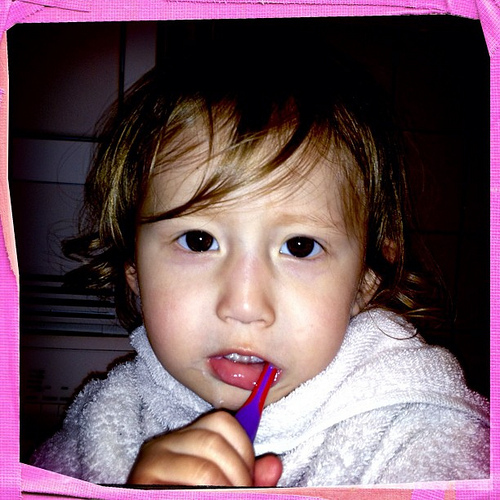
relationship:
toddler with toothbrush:
[18, 32, 481, 474] [227, 350, 286, 449]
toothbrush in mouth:
[227, 350, 286, 449] [210, 345, 282, 388]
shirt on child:
[88, 322, 460, 482] [18, 32, 481, 474]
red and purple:
[258, 387, 269, 412] [245, 406, 257, 429]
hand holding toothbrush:
[139, 409, 257, 488] [227, 350, 286, 449]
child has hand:
[18, 32, 481, 474] [139, 409, 257, 488]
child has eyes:
[18, 32, 481, 474] [174, 230, 329, 264]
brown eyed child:
[187, 232, 214, 249] [18, 32, 481, 474]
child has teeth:
[18, 32, 481, 474] [224, 350, 268, 366]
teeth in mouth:
[224, 350, 268, 366] [210, 345, 282, 388]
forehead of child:
[166, 114, 341, 208] [18, 32, 481, 474]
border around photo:
[2, 1, 498, 31] [18, 32, 481, 474]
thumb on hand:
[256, 449, 283, 485] [139, 409, 257, 488]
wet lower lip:
[228, 367, 257, 383] [214, 357, 265, 387]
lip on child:
[214, 357, 265, 387] [18, 32, 481, 474]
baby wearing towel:
[18, 32, 481, 474] [88, 322, 460, 482]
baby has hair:
[18, 32, 481, 474] [95, 63, 430, 318]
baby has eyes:
[18, 32, 481, 474] [174, 230, 329, 264]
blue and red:
[241, 406, 255, 433] [258, 387, 269, 412]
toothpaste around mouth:
[186, 351, 209, 380] [210, 345, 282, 388]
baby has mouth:
[18, 32, 481, 474] [210, 345, 282, 388]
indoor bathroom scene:
[17, 39, 489, 475] [14, 26, 484, 500]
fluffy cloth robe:
[369, 340, 447, 448] [88, 322, 460, 482]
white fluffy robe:
[348, 352, 398, 401] [88, 322, 460, 482]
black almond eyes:
[187, 232, 214, 249] [174, 230, 329, 264]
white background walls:
[23, 30, 94, 173] [14, 28, 141, 353]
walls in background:
[14, 28, 141, 353] [24, 29, 495, 234]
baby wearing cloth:
[18, 32, 481, 474] [88, 322, 460, 482]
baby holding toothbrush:
[18, 32, 481, 474] [227, 350, 286, 449]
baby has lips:
[18, 32, 481, 474] [210, 345, 282, 388]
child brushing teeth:
[18, 32, 481, 474] [224, 350, 268, 366]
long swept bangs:
[190, 89, 305, 205] [133, 91, 367, 199]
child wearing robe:
[18, 32, 481, 474] [88, 322, 460, 482]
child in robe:
[18, 32, 481, 474] [88, 322, 460, 482]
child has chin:
[18, 32, 481, 474] [203, 378, 283, 419]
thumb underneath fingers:
[256, 449, 283, 485] [139, 409, 257, 488]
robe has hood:
[88, 322, 460, 482] [351, 317, 479, 417]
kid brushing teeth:
[18, 32, 481, 474] [224, 350, 268, 366]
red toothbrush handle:
[258, 387, 269, 412] [243, 354, 276, 425]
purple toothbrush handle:
[245, 406, 257, 429] [243, 354, 276, 425]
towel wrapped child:
[88, 322, 460, 482] [18, 32, 481, 474]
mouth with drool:
[210, 345, 282, 388] [194, 358, 229, 411]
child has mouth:
[18, 32, 481, 474] [210, 345, 282, 388]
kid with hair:
[18, 32, 481, 474] [95, 63, 430, 318]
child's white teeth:
[18, 32, 481, 474] [224, 350, 268, 366]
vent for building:
[25, 265, 126, 342] [23, 94, 134, 371]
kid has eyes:
[18, 32, 481, 474] [174, 230, 329, 264]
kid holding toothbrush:
[18, 32, 481, 474] [227, 350, 286, 449]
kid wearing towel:
[18, 32, 481, 474] [88, 322, 460, 482]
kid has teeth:
[18, 32, 481, 474] [224, 350, 268, 366]